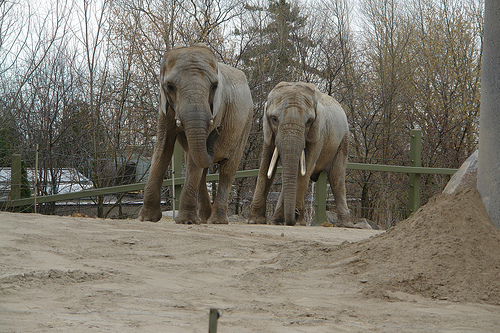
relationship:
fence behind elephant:
[2, 156, 459, 239] [140, 44, 250, 226]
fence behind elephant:
[2, 156, 459, 239] [245, 80, 355, 229]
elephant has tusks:
[245, 80, 355, 229] [262, 140, 309, 181]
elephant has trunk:
[140, 44, 250, 226] [269, 109, 314, 224]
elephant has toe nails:
[140, 44, 250, 226] [129, 208, 210, 225]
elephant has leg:
[245, 80, 355, 229] [325, 132, 363, 229]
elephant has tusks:
[138, 43, 254, 225] [258, 138, 312, 181]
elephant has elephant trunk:
[138, 43, 254, 225] [177, 103, 227, 172]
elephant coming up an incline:
[138, 43, 254, 225] [96, 200, 388, 271]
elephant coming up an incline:
[245, 80, 355, 229] [96, 200, 388, 271]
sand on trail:
[2, 212, 497, 332] [88, 226, 355, 326]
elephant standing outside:
[244, 82, 351, 224] [18, 13, 170, 193]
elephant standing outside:
[140, 44, 250, 226] [18, 13, 170, 193]